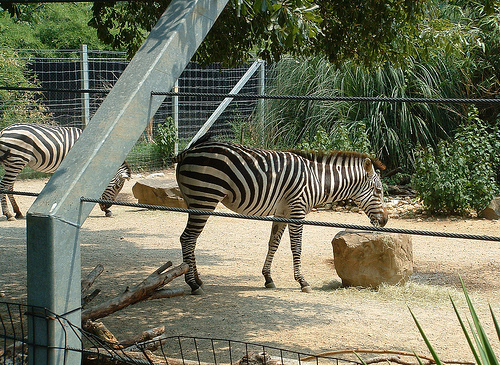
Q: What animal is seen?
A: Zebras.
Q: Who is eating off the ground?
A: Zebras.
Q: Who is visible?
A: Zebras.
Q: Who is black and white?
A: Zebras.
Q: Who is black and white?
A: Zebras.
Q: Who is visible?
A: Zebras.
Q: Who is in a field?
A: Zebras.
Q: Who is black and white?
A: Zebras.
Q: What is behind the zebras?
A: A fence.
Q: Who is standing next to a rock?
A: A zebra.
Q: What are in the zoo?
A: Zebra.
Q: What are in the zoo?
A: Animals.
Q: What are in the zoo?
A: Legs.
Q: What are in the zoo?
A: Trees.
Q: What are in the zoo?
A: Conainers.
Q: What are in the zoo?
A: Stone.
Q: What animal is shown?
A: Zebras.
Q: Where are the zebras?
A: In the zoo.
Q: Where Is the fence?
A: Around the zebras.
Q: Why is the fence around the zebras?
A: To keep them in.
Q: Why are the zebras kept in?
A: For entertainment.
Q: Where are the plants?
A: Around the zebras.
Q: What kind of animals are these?
A: Zebras.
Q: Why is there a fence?
A: So they don't get out.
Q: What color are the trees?
A: Green.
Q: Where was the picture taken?
A: At a zoo.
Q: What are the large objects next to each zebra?
A: Rocks.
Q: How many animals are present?
A: Two.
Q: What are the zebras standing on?
A: The ground.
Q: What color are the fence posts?
A: Grey.